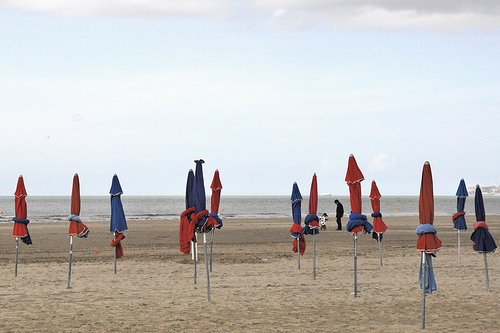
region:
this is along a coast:
[15, 42, 447, 280]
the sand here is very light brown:
[80, 268, 211, 330]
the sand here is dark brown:
[137, 225, 192, 251]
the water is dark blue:
[136, 190, 193, 222]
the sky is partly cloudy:
[33, 38, 302, 116]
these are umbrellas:
[47, 142, 432, 288]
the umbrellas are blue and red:
[65, 127, 300, 207]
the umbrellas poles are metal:
[163, 222, 250, 304]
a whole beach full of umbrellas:
[18, 153, 493, 296]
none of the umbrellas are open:
[1, 142, 478, 316]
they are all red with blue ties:
[12, 170, 496, 305]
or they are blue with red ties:
[103, 159, 264, 248]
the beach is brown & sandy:
[72, 259, 346, 316]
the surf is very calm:
[106, 185, 291, 207]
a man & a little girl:
[318, 199, 344, 239]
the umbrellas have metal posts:
[43, 239, 238, 304]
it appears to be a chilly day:
[135, 185, 483, 294]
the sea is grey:
[96, 191, 283, 203]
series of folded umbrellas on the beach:
[4, 148, 499, 330]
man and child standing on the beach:
[320, 198, 349, 231]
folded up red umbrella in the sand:
[11, 170, 43, 250]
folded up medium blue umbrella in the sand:
[105, 171, 130, 274]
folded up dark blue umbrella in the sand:
[468, 179, 496, 253]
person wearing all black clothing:
[332, 197, 347, 229]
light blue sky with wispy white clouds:
[82, 24, 432, 151]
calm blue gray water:
[224, 195, 286, 214]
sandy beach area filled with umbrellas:
[228, 280, 358, 325]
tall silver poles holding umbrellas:
[69, 230, 75, 292]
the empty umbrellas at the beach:
[12, 154, 497, 329]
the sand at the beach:
[0, 214, 498, 331]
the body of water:
[0, 193, 498, 223]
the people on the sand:
[319, 198, 344, 230]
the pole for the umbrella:
[482, 252, 489, 292]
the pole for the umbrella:
[202, 232, 210, 301]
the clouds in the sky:
[0, 0, 498, 196]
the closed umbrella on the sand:
[11, 173, 33, 276]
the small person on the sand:
[319, 212, 329, 230]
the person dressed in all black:
[333, 198, 343, 230]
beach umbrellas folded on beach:
[14, 135, 497, 331]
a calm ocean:
[6, 178, 496, 222]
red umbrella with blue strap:
[7, 169, 54, 290]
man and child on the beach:
[322, 178, 354, 263]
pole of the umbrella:
[66, 231, 83, 303]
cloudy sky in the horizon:
[9, 63, 482, 167]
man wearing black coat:
[332, 185, 350, 238]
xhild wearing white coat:
[323, 206, 332, 241]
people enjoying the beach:
[318, 184, 348, 255]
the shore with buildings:
[463, 163, 499, 222]